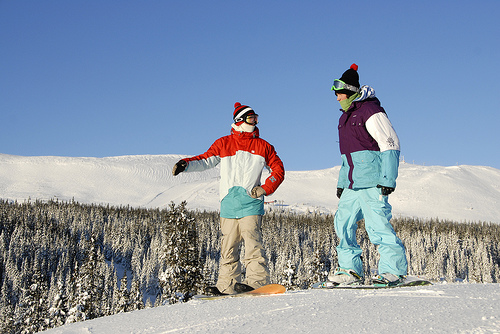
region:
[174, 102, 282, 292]
this is a man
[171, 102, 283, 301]
the man is standing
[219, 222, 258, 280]
this is the trousers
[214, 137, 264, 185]
this is the jacket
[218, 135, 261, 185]
the jacket is warm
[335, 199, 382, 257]
the trousers is blue in color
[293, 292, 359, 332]
the snow is on the ground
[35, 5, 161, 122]
this is the sky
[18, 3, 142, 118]
the sky is clear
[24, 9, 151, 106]
the sky is blue in color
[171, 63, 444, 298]
two skiboarders on top of the ski run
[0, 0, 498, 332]
two skiboarders on sunny mountain top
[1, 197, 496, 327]
forest of snow covered trees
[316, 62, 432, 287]
skiboarder in turqoise purple and white outfit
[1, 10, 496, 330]
view from the ski resort mountaintop on sunny day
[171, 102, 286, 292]
snowboarder in red white and turqoise parka and khaki snowpants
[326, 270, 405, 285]
white snowboard boots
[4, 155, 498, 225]
snow covered mountains above the tree line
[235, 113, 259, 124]
pair of ski goggles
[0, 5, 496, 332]
snowboarders prepare to go down the mountain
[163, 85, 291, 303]
fully clothes snow boarder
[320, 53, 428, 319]
snow boarder with goggles up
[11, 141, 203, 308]
snow hills and trees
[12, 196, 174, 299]
forest of trees dusted with snow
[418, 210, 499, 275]
forest of trees covered in white snow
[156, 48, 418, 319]
two friends getting ready to go down the hill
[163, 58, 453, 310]
coming up with a plan of attack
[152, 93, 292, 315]
explaining where they should snow board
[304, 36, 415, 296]
person with a black hat and red ball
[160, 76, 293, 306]
person wearing tan snow pants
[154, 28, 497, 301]
men on a snowboard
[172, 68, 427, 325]
men on a mountain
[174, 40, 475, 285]
men on a snowcovered mountain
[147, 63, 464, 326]
men standing on snowboards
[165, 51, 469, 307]
men wearing halts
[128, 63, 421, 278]
two men wearing hats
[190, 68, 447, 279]
two men wearing googles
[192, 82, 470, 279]
two men wearing jackets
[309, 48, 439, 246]
a man wearing blue pants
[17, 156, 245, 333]
trees covered in snow